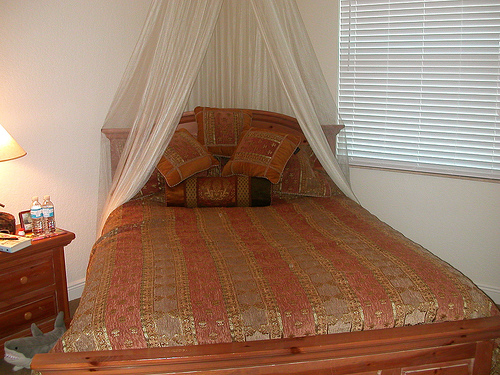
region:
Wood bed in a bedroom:
[32, 122, 498, 370]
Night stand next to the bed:
[0, 222, 76, 355]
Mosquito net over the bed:
[95, 1, 362, 238]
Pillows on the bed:
[152, 106, 331, 206]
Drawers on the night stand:
[2, 258, 62, 346]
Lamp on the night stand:
[0, 126, 26, 211]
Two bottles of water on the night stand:
[30, 193, 55, 233]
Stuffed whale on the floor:
[2, 310, 66, 373]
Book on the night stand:
[0, 232, 33, 254]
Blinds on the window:
[337, 0, 498, 182]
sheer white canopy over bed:
[87, 0, 367, 225]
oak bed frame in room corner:
[39, 109, 496, 371]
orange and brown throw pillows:
[118, 102, 336, 207]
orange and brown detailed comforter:
[67, 196, 493, 356]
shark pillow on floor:
[1, 307, 71, 373]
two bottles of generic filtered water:
[29, 192, 57, 236]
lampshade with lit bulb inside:
[0, 120, 31, 166]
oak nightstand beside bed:
[1, 228, 71, 343]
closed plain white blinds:
[340, 2, 498, 181]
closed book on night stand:
[1, 227, 31, 255]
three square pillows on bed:
[149, 87, 298, 179]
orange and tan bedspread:
[53, 174, 471, 356]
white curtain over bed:
[48, 1, 304, 211]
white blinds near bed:
[339, 9, 499, 169]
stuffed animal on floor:
[10, 310, 59, 362]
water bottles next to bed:
[32, 194, 60, 236]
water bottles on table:
[4, 189, 80, 344]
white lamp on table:
[6, 141, 50, 161]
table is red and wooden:
[2, 222, 78, 345]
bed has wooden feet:
[37, 316, 496, 368]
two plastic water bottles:
[27, 191, 73, 238]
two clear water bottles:
[27, 193, 69, 242]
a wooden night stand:
[0, 210, 76, 352]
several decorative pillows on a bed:
[114, 107, 331, 227]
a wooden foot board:
[70, 302, 499, 369]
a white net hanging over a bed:
[113, 19, 313, 237]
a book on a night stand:
[0, 222, 32, 259]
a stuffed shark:
[1, 303, 73, 373]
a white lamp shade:
[0, 98, 25, 192]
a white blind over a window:
[320, 25, 467, 176]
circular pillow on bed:
[162, 179, 282, 204]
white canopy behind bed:
[242, 5, 287, 72]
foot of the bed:
[272, 347, 425, 374]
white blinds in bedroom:
[432, 35, 492, 130]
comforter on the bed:
[160, 221, 286, 306]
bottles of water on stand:
[32, 197, 55, 234]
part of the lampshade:
[0, 124, 32, 164]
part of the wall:
[402, 181, 460, 243]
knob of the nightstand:
[15, 267, 38, 291]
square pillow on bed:
[199, 111, 246, 150]